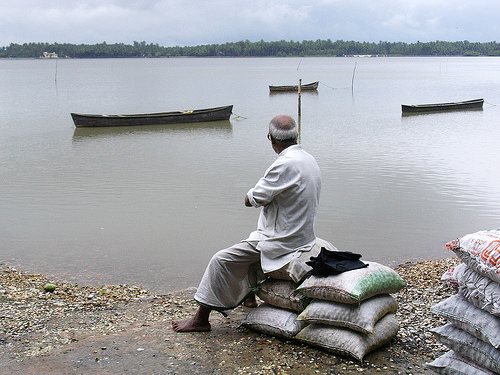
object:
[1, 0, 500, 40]
sky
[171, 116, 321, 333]
man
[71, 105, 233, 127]
boat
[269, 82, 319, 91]
boat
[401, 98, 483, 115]
boat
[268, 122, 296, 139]
hair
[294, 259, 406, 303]
sack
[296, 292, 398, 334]
sack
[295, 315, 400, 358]
sack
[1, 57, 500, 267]
lake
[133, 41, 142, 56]
trees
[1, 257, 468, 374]
beach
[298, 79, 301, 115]
docking pole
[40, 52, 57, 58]
home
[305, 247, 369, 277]
item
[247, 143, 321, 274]
white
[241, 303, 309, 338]
sack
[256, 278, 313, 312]
sack